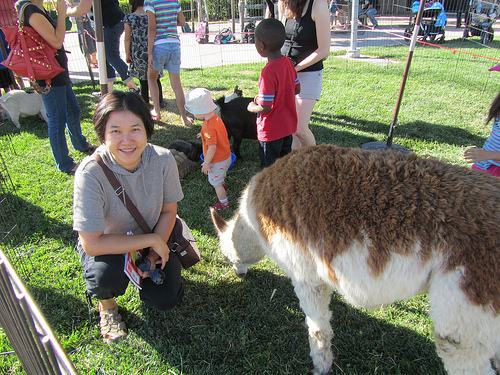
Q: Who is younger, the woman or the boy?
A: The boy is younger than the woman.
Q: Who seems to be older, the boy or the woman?
A: The woman is older than the boy.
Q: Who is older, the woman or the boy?
A: The woman is older than the boy.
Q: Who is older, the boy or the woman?
A: The woman is older than the boy.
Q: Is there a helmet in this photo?
A: No, there are no helmets.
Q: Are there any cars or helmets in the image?
A: No, there are no helmets or cars.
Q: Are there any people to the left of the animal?
A: Yes, there is a person to the left of the animal.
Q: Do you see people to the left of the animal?
A: Yes, there is a person to the left of the animal.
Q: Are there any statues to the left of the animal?
A: No, there is a person to the left of the animal.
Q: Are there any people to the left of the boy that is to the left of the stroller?
A: Yes, there is a person to the left of the boy.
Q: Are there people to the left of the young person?
A: Yes, there is a person to the left of the boy.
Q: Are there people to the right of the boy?
A: No, the person is to the left of the boy.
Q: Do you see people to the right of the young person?
A: No, the person is to the left of the boy.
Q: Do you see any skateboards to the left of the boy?
A: No, there is a person to the left of the boy.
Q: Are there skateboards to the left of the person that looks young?
A: No, there is a person to the left of the boy.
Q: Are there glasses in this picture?
A: No, there are no glasses.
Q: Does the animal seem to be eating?
A: Yes, the animal is eating.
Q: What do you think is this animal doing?
A: The animal is eating.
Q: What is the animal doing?
A: The animal is eating.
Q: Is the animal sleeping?
A: No, the animal is eating.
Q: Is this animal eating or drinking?
A: The animal is eating.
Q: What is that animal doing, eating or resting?
A: The animal is eating.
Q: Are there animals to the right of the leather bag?
A: Yes, there is an animal to the right of the bag.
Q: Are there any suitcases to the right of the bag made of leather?
A: No, there is an animal to the right of the bag.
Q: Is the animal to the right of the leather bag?
A: Yes, the animal is to the right of the bag.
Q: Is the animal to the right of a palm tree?
A: No, the animal is to the right of the bag.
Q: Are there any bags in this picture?
A: Yes, there is a bag.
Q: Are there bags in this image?
A: Yes, there is a bag.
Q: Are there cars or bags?
A: Yes, there is a bag.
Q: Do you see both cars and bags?
A: No, there is a bag but no cars.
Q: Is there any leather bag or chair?
A: Yes, there is a leather bag.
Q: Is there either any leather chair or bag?
A: Yes, there is a leather bag.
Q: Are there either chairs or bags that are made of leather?
A: Yes, the bag is made of leather.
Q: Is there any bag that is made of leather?
A: Yes, there is a bag that is made of leather.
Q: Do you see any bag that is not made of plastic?
A: Yes, there is a bag that is made of leather.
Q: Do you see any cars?
A: No, there are no cars.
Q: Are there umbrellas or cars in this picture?
A: No, there are no cars or umbrellas.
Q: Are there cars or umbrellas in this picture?
A: No, there are no cars or umbrellas.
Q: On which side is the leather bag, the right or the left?
A: The bag is on the left of the image.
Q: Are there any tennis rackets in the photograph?
A: No, there are no tennis rackets.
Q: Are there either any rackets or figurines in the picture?
A: No, there are no rackets or figurines.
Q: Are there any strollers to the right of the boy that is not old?
A: Yes, there is a stroller to the right of the boy.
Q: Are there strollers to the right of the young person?
A: Yes, there is a stroller to the right of the boy.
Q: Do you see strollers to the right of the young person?
A: Yes, there is a stroller to the right of the boy.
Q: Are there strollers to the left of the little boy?
A: No, the stroller is to the right of the boy.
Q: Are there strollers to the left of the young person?
A: No, the stroller is to the right of the boy.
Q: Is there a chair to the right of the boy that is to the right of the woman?
A: No, there is a stroller to the right of the boy.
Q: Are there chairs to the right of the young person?
A: No, there is a stroller to the right of the boy.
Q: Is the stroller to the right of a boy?
A: Yes, the stroller is to the right of a boy.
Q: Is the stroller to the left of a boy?
A: No, the stroller is to the right of a boy.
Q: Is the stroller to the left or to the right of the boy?
A: The stroller is to the right of the boy.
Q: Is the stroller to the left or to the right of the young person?
A: The stroller is to the right of the boy.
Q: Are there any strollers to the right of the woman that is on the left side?
A: Yes, there is a stroller to the right of the woman.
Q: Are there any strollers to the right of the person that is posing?
A: Yes, there is a stroller to the right of the woman.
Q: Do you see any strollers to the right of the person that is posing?
A: Yes, there is a stroller to the right of the woman.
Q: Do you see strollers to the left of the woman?
A: No, the stroller is to the right of the woman.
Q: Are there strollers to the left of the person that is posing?
A: No, the stroller is to the right of the woman.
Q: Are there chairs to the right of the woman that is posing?
A: No, there is a stroller to the right of the woman.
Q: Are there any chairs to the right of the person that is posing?
A: No, there is a stroller to the right of the woman.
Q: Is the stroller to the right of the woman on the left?
A: Yes, the stroller is to the right of the woman.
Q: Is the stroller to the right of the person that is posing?
A: Yes, the stroller is to the right of the woman.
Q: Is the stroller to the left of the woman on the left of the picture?
A: No, the stroller is to the right of the woman.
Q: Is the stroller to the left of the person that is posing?
A: No, the stroller is to the right of the woman.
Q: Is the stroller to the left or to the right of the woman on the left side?
A: The stroller is to the right of the woman.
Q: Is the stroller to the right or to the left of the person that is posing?
A: The stroller is to the right of the woman.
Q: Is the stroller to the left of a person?
A: No, the stroller is to the right of a person.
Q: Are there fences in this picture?
A: Yes, there is a fence.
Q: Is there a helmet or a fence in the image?
A: Yes, there is a fence.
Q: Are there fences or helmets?
A: Yes, there is a fence.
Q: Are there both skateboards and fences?
A: No, there is a fence but no skateboards.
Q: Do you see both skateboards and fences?
A: No, there is a fence but no skateboards.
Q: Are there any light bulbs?
A: No, there are no light bulbs.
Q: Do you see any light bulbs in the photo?
A: No, there are no light bulbs.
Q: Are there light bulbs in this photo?
A: No, there are no light bulbs.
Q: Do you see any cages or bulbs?
A: No, there are no bulbs or cages.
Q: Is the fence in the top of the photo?
A: Yes, the fence is in the top of the image.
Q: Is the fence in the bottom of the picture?
A: No, the fence is in the top of the image.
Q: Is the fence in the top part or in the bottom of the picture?
A: The fence is in the top of the image.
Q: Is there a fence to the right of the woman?
A: Yes, there is a fence to the right of the woman.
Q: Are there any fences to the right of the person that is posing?
A: Yes, there is a fence to the right of the woman.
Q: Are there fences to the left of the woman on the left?
A: No, the fence is to the right of the woman.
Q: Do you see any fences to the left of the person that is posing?
A: No, the fence is to the right of the woman.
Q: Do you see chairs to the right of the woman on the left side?
A: No, there is a fence to the right of the woman.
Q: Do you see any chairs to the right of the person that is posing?
A: No, there is a fence to the right of the woman.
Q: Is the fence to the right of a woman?
A: Yes, the fence is to the right of a woman.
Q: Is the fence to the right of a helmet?
A: No, the fence is to the right of a woman.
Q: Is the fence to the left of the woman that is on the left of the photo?
A: No, the fence is to the right of the woman.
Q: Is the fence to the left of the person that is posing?
A: No, the fence is to the right of the woman.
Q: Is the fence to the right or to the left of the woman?
A: The fence is to the right of the woman.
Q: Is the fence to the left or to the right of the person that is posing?
A: The fence is to the right of the woman.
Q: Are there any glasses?
A: No, there are no glasses.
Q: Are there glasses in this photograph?
A: No, there are no glasses.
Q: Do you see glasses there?
A: No, there are no glasses.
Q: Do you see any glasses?
A: No, there are no glasses.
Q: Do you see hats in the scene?
A: Yes, there is a hat.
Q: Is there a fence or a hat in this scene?
A: Yes, there is a hat.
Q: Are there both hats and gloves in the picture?
A: No, there is a hat but no gloves.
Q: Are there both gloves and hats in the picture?
A: No, there is a hat but no gloves.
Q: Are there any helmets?
A: No, there are no helmets.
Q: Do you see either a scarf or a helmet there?
A: No, there are no helmets or scarves.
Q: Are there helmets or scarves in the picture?
A: No, there are no helmets or scarves.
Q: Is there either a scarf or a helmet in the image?
A: No, there are no helmets or scarves.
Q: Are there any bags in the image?
A: Yes, there is a bag.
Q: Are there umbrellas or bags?
A: Yes, there is a bag.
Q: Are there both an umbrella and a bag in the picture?
A: No, there is a bag but no umbrellas.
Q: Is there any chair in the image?
A: No, there are no chairs.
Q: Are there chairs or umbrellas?
A: No, there are no chairs or umbrellas.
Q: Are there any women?
A: Yes, there is a woman.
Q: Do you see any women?
A: Yes, there is a woman.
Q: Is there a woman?
A: Yes, there is a woman.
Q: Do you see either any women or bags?
A: Yes, there is a woman.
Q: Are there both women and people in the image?
A: Yes, there are both a woman and a person.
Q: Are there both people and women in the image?
A: Yes, there are both a woman and a person.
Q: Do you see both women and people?
A: Yes, there are both a woman and a person.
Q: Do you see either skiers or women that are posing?
A: Yes, the woman is posing.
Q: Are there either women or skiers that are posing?
A: Yes, the woman is posing.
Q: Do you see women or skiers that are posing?
A: Yes, the woman is posing.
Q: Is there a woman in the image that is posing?
A: Yes, there is a woman that is posing.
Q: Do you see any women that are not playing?
A: Yes, there is a woman that is posing .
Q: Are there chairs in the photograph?
A: No, there are no chairs.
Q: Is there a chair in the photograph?
A: No, there are no chairs.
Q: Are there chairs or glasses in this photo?
A: No, there are no chairs or glasses.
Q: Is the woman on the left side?
A: Yes, the woman is on the left of the image.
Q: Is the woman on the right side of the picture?
A: No, the woman is on the left of the image.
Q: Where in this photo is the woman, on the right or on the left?
A: The woman is on the left of the image.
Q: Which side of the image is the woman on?
A: The woman is on the left of the image.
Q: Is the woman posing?
A: Yes, the woman is posing.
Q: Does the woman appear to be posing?
A: Yes, the woman is posing.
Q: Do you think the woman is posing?
A: Yes, the woman is posing.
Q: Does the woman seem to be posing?
A: Yes, the woman is posing.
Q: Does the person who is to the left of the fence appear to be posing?
A: Yes, the woman is posing.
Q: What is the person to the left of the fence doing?
A: The woman is posing.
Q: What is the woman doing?
A: The woman is posing.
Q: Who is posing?
A: The woman is posing.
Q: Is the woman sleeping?
A: No, the woman is posing.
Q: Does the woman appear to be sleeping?
A: No, the woman is posing.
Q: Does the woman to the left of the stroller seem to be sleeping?
A: No, the woman is posing.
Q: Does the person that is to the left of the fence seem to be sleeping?
A: No, the woman is posing.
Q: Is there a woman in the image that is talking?
A: No, there is a woman but she is posing.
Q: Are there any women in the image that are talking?
A: No, there is a woman but she is posing.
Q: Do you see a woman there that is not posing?
A: No, there is a woman but she is posing.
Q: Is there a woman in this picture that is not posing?
A: No, there is a woman but she is posing.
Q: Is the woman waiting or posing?
A: The woman is posing.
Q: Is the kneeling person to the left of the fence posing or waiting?
A: The woman is posing.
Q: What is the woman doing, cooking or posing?
A: The woman is posing.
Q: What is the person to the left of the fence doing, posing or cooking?
A: The woman is posing.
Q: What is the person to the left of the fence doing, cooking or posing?
A: The woman is posing.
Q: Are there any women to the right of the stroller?
A: No, the woman is to the left of the stroller.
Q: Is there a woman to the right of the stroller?
A: No, the woman is to the left of the stroller.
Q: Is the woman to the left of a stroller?
A: Yes, the woman is to the left of a stroller.